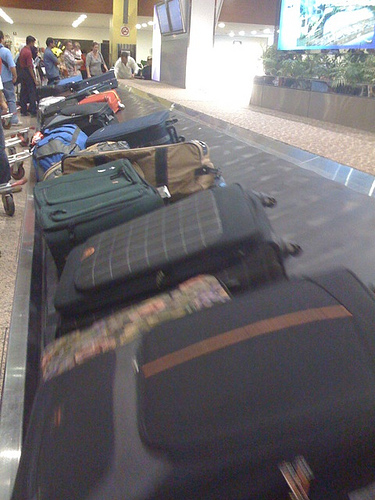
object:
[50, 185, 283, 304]
suitcase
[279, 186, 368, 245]
belt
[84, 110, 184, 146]
suitcase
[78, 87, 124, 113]
suitcase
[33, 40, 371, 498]
baggage claim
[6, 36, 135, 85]
people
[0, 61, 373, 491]
luggage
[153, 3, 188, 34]
moniter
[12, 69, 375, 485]
carousel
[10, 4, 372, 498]
airport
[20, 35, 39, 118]
man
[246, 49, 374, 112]
planter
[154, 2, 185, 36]
flight information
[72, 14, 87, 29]
ceiling light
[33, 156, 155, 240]
suitcase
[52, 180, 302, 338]
pocket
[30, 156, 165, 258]
luggage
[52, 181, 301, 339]
luggage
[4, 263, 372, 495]
luggage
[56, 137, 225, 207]
luggage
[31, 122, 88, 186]
luggage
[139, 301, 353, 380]
stripe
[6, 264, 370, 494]
suitcase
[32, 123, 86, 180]
bag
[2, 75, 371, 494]
conveyor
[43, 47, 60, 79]
shirt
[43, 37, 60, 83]
man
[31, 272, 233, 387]
suitcase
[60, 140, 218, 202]
suitcase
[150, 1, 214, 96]
wall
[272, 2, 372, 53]
monitor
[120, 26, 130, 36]
sign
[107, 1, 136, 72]
wall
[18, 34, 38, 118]
man wearing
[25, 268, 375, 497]
black luggage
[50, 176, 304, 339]
black luggage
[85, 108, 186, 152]
black luggage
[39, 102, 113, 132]
black luggage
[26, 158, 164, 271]
green luggage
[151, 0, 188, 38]
screen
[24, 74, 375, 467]
luggage carousel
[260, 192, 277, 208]
luggage wheel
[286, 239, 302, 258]
luggage wheel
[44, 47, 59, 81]
blue shirt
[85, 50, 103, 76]
woman wearing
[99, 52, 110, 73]
handbag